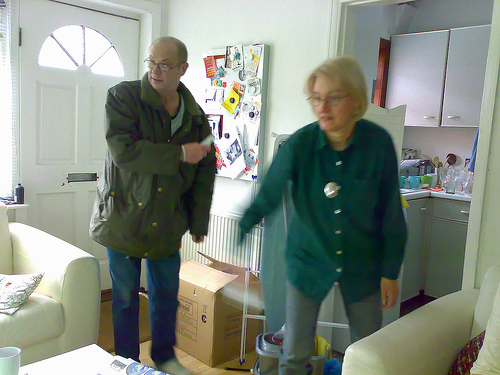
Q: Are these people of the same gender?
A: No, they are both male and female.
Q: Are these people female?
A: No, they are both male and female.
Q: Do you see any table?
A: Yes, there is a table.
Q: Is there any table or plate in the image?
A: Yes, there is a table.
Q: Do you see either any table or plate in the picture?
A: Yes, there is a table.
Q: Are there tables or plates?
A: Yes, there is a table.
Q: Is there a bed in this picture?
A: No, there are no beds.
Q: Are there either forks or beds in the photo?
A: No, there are no beds or forks.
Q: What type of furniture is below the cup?
A: The piece of furniture is a table.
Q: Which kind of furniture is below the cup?
A: The piece of furniture is a table.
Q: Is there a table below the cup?
A: Yes, there is a table below the cup.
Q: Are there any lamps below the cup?
A: No, there is a table below the cup.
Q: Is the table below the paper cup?
A: Yes, the table is below the cup.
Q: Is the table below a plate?
A: No, the table is below the cup.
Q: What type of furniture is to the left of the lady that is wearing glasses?
A: The piece of furniture is a table.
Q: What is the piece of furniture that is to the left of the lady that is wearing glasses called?
A: The piece of furniture is a table.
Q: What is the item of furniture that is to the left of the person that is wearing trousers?
A: The piece of furniture is a table.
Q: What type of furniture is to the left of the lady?
A: The piece of furniture is a table.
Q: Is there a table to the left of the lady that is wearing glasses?
A: Yes, there is a table to the left of the lady.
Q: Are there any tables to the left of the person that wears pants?
A: Yes, there is a table to the left of the lady.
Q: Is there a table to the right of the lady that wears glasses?
A: No, the table is to the left of the lady.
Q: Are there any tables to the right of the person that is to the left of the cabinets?
A: No, the table is to the left of the lady.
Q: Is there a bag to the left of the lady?
A: No, there is a table to the left of the lady.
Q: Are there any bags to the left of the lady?
A: No, there is a table to the left of the lady.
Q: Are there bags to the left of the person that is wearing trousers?
A: No, there is a table to the left of the lady.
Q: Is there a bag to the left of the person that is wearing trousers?
A: No, there is a table to the left of the lady.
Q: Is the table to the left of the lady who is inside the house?
A: Yes, the table is to the left of the lady.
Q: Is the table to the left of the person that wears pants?
A: Yes, the table is to the left of the lady.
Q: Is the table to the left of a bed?
A: No, the table is to the left of the lady.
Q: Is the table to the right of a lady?
A: No, the table is to the left of a lady.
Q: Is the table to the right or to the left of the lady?
A: The table is to the left of the lady.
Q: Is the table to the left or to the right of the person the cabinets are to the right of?
A: The table is to the left of the lady.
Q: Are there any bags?
A: No, there are no bags.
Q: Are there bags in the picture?
A: No, there are no bags.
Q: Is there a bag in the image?
A: No, there are no bags.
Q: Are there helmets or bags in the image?
A: No, there are no bags or helmets.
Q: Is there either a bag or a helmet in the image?
A: No, there are no bags or helmets.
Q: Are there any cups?
A: Yes, there is a cup.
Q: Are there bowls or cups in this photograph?
A: Yes, there is a cup.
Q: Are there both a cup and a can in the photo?
A: No, there is a cup but no cans.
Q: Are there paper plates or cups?
A: Yes, there is a paper cup.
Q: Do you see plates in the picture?
A: No, there are no plates.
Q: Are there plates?
A: No, there are no plates.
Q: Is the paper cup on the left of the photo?
A: Yes, the cup is on the left of the image.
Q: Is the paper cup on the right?
A: No, the cup is on the left of the image.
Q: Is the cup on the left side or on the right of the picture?
A: The cup is on the left of the image.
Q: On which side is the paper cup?
A: The cup is on the left of the image.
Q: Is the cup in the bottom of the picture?
A: Yes, the cup is in the bottom of the image.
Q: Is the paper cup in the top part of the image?
A: No, the cup is in the bottom of the image.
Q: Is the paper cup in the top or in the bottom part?
A: The cup is in the bottom of the image.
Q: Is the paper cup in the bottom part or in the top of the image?
A: The cup is in the bottom of the image.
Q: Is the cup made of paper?
A: Yes, the cup is made of paper.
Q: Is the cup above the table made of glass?
A: No, the cup is made of paper.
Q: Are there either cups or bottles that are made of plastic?
A: No, there is a cup but it is made of paper.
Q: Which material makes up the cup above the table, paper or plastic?
A: The cup is made of paper.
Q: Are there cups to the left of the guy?
A: Yes, there is a cup to the left of the guy.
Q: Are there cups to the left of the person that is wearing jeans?
A: Yes, there is a cup to the left of the guy.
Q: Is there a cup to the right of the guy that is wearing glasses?
A: No, the cup is to the left of the guy.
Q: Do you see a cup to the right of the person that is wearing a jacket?
A: No, the cup is to the left of the guy.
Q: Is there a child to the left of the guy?
A: No, there is a cup to the left of the guy.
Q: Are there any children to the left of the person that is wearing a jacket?
A: No, there is a cup to the left of the guy.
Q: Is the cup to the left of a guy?
A: Yes, the cup is to the left of a guy.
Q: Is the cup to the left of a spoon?
A: No, the cup is to the left of a guy.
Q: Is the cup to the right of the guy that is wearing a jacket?
A: No, the cup is to the left of the guy.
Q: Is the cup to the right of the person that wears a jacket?
A: No, the cup is to the left of the guy.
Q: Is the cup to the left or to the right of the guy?
A: The cup is to the left of the guy.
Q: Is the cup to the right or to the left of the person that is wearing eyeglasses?
A: The cup is to the left of the guy.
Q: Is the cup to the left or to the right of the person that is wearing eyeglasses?
A: The cup is to the left of the guy.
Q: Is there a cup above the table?
A: Yes, there is a cup above the table.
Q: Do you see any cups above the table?
A: Yes, there is a cup above the table.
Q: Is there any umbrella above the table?
A: No, there is a cup above the table.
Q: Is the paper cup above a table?
A: Yes, the cup is above a table.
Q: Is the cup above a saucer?
A: No, the cup is above a table.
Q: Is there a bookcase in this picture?
A: No, there are no bookcases.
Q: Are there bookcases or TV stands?
A: No, there are no bookcases or TV stands.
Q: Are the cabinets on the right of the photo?
A: Yes, the cabinets are on the right of the image.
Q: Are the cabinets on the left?
A: No, the cabinets are on the right of the image.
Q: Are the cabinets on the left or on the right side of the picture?
A: The cabinets are on the right of the image.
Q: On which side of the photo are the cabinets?
A: The cabinets are on the right of the image.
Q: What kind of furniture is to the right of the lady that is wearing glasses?
A: The pieces of furniture are cabinets.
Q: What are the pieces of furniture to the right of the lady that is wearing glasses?
A: The pieces of furniture are cabinets.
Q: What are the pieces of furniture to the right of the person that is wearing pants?
A: The pieces of furniture are cabinets.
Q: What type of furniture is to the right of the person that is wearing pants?
A: The pieces of furniture are cabinets.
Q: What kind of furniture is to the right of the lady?
A: The pieces of furniture are cabinets.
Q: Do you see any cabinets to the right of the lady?
A: Yes, there are cabinets to the right of the lady.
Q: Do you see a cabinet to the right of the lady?
A: Yes, there are cabinets to the right of the lady.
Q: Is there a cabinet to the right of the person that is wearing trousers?
A: Yes, there are cabinets to the right of the lady.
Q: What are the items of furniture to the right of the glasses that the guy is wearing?
A: The pieces of furniture are cabinets.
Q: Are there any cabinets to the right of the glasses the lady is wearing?
A: Yes, there are cabinets to the right of the glasses.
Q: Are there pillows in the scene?
A: Yes, there is a pillow.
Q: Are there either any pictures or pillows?
A: Yes, there is a pillow.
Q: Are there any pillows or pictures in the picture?
A: Yes, there is a pillow.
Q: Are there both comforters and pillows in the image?
A: No, there is a pillow but no comforters.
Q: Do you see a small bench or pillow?
A: Yes, there is a small pillow.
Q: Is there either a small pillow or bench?
A: Yes, there is a small pillow.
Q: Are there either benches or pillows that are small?
A: Yes, the pillow is small.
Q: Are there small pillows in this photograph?
A: Yes, there is a small pillow.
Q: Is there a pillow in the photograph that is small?
A: Yes, there is a pillow that is small.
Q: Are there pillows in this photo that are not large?
A: Yes, there is a small pillow.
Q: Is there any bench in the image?
A: No, there are no benches.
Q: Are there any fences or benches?
A: No, there are no benches or fences.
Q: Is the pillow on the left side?
A: Yes, the pillow is on the left of the image.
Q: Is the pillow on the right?
A: No, the pillow is on the left of the image.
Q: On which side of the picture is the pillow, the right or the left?
A: The pillow is on the left of the image.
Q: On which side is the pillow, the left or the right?
A: The pillow is on the left of the image.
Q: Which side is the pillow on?
A: The pillow is on the left of the image.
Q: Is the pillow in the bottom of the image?
A: Yes, the pillow is in the bottom of the image.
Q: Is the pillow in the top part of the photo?
A: No, the pillow is in the bottom of the image.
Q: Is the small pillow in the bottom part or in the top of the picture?
A: The pillow is in the bottom of the image.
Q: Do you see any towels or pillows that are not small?
A: No, there is a pillow but it is small.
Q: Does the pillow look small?
A: Yes, the pillow is small.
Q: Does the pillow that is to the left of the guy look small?
A: Yes, the pillow is small.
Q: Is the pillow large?
A: No, the pillow is small.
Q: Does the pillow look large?
A: No, the pillow is small.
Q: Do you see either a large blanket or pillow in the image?
A: No, there is a pillow but it is small.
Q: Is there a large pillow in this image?
A: No, there is a pillow but it is small.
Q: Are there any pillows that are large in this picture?
A: No, there is a pillow but it is small.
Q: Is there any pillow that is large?
A: No, there is a pillow but it is small.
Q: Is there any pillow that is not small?
A: No, there is a pillow but it is small.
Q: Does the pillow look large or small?
A: The pillow is small.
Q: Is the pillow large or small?
A: The pillow is small.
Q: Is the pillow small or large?
A: The pillow is small.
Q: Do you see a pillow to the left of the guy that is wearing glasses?
A: Yes, there is a pillow to the left of the guy.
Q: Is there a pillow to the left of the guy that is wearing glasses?
A: Yes, there is a pillow to the left of the guy.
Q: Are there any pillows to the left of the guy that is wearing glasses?
A: Yes, there is a pillow to the left of the guy.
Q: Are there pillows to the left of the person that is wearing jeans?
A: Yes, there is a pillow to the left of the guy.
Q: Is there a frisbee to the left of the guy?
A: No, there is a pillow to the left of the guy.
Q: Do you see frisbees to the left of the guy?
A: No, there is a pillow to the left of the guy.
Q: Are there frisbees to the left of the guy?
A: No, there is a pillow to the left of the guy.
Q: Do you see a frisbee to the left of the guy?
A: No, there is a pillow to the left of the guy.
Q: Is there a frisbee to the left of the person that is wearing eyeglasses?
A: No, there is a pillow to the left of the guy.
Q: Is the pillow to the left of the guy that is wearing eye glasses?
A: Yes, the pillow is to the left of the guy.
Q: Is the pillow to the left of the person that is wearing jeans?
A: Yes, the pillow is to the left of the guy.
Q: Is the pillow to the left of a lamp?
A: No, the pillow is to the left of the guy.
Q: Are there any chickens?
A: No, there are no chickens.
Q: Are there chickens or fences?
A: No, there are no chickens or fences.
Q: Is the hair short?
A: Yes, the hair is short.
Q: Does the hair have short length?
A: Yes, the hair is short.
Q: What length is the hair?
A: The hair is short.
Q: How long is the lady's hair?
A: The hair is short.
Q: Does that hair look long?
A: No, the hair is short.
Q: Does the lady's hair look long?
A: No, the hair is short.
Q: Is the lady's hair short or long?
A: The hair is short.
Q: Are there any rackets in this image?
A: No, there are no rackets.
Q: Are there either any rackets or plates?
A: No, there are no rackets or plates.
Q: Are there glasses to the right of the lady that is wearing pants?
A: Yes, there are glasses to the right of the lady.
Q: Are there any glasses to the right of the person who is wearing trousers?
A: Yes, there are glasses to the right of the lady.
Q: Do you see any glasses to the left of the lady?
A: No, the glasses are to the right of the lady.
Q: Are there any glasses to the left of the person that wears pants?
A: No, the glasses are to the right of the lady.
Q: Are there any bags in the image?
A: No, there are no bags.